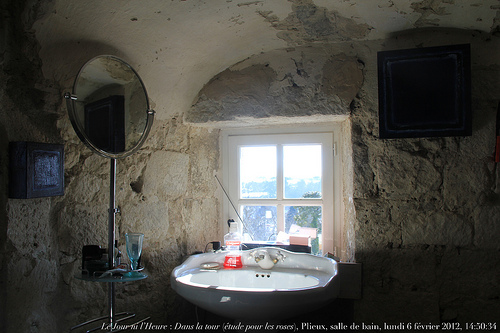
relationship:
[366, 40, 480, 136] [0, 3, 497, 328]
box on wall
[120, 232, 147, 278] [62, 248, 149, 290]
glass on a shelf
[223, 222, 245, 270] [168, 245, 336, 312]
bottle on sink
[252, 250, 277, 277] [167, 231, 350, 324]
faucet on sink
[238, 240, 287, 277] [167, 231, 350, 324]
handles on sink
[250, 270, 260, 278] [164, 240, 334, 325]
hole in basin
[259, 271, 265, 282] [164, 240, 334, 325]
hole in basin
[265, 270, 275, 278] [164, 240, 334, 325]
hole in basin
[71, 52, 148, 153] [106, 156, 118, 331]
mirror on pole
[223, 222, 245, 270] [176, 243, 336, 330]
bottle on sink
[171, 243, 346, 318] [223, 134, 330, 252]
sink beside window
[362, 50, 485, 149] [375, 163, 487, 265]
television on a wall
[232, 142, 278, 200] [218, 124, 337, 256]
pane on window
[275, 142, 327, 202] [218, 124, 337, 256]
pane on window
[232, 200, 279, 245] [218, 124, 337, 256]
pane on window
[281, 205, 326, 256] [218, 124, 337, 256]
pane on window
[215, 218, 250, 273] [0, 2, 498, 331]
bottle in photo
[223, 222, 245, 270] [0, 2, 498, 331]
bottle in photo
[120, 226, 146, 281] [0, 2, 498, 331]
glass in photo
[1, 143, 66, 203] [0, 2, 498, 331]
cabinet in photo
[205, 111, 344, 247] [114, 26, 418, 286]
window frame on wall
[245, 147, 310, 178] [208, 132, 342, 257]
light outside window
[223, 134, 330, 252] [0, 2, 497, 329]
window in bathroom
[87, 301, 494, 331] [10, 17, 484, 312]
photo tag on picture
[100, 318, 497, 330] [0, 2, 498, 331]
words on photo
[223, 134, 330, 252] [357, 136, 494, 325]
window next to wall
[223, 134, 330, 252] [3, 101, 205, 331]
window next to wall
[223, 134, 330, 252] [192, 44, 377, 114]
window next to wall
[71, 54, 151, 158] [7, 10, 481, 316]
mirror in room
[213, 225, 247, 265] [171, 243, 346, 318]
item next to sink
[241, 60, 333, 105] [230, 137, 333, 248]
wall above window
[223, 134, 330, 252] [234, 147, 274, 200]
window with pane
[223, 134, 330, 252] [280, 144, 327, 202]
window with pane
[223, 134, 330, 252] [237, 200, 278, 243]
window with pane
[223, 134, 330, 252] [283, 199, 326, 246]
window with pane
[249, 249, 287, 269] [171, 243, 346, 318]
faucet of sink